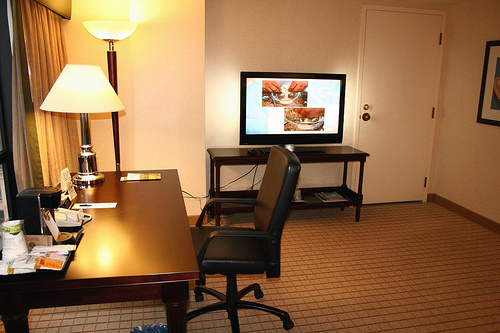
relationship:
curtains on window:
[1, 1, 91, 199] [4, 9, 60, 247]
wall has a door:
[68, 0, 445, 210] [355, 2, 439, 208]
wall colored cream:
[68, 0, 445, 210] [135, 47, 202, 163]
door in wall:
[355, 2, 439, 208] [68, 0, 445, 210]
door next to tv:
[355, 2, 439, 208] [236, 67, 347, 141]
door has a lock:
[355, 2, 439, 208] [359, 99, 381, 126]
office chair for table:
[190, 136, 298, 330] [1, 169, 206, 333]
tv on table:
[236, 67, 347, 141] [206, 145, 370, 227]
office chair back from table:
[190, 136, 298, 330] [1, 169, 206, 333]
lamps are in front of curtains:
[40, 9, 152, 187] [1, 1, 91, 199]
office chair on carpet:
[190, 136, 298, 330] [14, 192, 500, 332]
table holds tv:
[206, 145, 370, 227] [236, 67, 347, 141]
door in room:
[355, 2, 439, 208] [2, 7, 498, 332]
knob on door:
[362, 104, 374, 126] [355, 2, 439, 208]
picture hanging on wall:
[476, 32, 498, 135] [434, 10, 498, 229]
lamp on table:
[42, 60, 124, 187] [1, 169, 206, 333]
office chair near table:
[190, 136, 298, 330] [1, 169, 206, 333]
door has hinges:
[355, 2, 439, 208] [422, 23, 445, 194]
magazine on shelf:
[315, 190, 352, 204] [223, 190, 358, 208]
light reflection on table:
[71, 212, 133, 276] [1, 169, 206, 333]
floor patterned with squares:
[14, 192, 500, 332] [299, 215, 489, 322]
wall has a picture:
[434, 10, 498, 229] [476, 32, 498, 135]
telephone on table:
[47, 196, 96, 229] [1, 169, 206, 333]